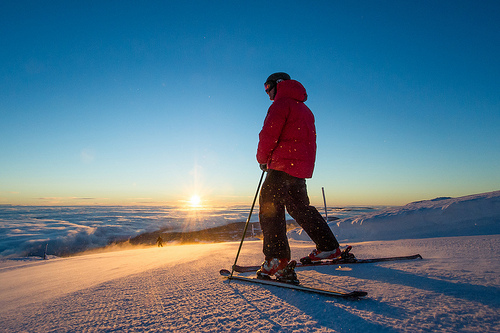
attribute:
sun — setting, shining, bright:
[175, 194, 216, 219]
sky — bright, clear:
[0, 0, 499, 211]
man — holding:
[250, 57, 358, 277]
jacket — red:
[255, 85, 326, 179]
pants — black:
[253, 166, 334, 262]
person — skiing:
[151, 232, 170, 253]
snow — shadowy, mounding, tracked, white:
[22, 238, 497, 330]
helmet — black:
[260, 69, 294, 84]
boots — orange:
[249, 236, 365, 287]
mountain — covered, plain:
[82, 214, 483, 323]